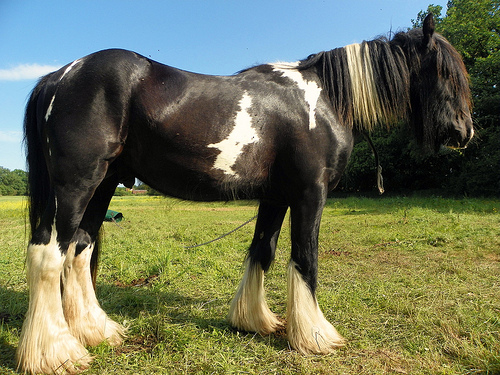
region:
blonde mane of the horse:
[336, 36, 386, 130]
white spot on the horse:
[200, 88, 262, 197]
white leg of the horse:
[283, 257, 343, 363]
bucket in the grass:
[105, 206, 127, 225]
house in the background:
[118, 185, 155, 199]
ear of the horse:
[410, 14, 440, 35]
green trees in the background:
[448, 7, 495, 48]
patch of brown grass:
[119, 317, 166, 359]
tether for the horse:
[175, 224, 240, 252]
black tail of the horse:
[13, 72, 52, 229]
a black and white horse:
[28, 6, 480, 326]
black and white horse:
[11, 8, 456, 371]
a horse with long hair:
[9, 5, 497, 351]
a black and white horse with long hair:
[4, 14, 474, 371]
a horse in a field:
[8, 7, 492, 358]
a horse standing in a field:
[34, 9, 489, 373]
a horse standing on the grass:
[29, 18, 471, 372]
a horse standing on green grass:
[4, 16, 496, 356]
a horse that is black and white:
[33, 1, 498, 303]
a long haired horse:
[28, 9, 464, 374]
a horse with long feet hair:
[19, 20, 494, 373]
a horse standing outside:
[11, 25, 497, 371]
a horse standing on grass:
[28, 20, 490, 373]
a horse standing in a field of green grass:
[24, 14, 443, 361]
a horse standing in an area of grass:
[32, 14, 465, 369]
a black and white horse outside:
[9, 6, 439, 372]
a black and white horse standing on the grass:
[28, 16, 442, 374]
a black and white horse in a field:
[18, 11, 467, 374]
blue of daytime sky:
[0, 1, 446, 107]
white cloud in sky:
[0, 62, 62, 81]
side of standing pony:
[18, 15, 472, 371]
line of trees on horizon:
[0, 166, 155, 195]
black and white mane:
[320, 39, 407, 123]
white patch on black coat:
[207, 92, 260, 174]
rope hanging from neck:
[353, 107, 388, 194]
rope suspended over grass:
[177, 207, 263, 257]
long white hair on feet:
[229, 258, 344, 353]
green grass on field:
[2, 193, 499, 371]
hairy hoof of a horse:
[19, 240, 92, 371]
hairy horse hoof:
[59, 243, 131, 347]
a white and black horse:
[20, 21, 473, 373]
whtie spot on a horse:
[205, 85, 265, 180]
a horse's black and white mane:
[308, 39, 408, 126]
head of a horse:
[397, 14, 474, 148]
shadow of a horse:
[0, 277, 302, 368]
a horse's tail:
[18, 70, 42, 246]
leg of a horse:
[279, 151, 339, 346]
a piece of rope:
[362, 130, 384, 192]